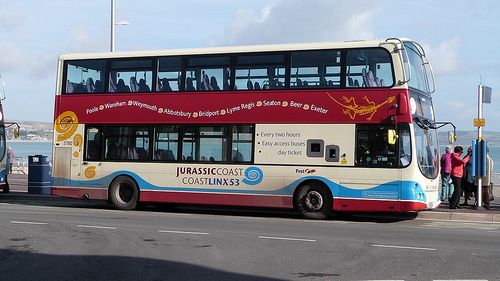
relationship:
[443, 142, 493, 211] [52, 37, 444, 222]
people near bus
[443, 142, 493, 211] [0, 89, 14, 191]
people near bus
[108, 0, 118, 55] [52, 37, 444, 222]
pole behind bus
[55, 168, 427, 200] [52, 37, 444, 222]
blue paint on bus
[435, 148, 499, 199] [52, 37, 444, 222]
group standing near bus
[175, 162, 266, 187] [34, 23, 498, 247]
advertisement on bus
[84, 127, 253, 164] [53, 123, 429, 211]
windows on deck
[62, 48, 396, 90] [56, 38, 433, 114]
windows in top deck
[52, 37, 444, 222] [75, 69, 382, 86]
bus showing passenger seats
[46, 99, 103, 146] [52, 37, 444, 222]
spiral on bus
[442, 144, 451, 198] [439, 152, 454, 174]
person wearing jacket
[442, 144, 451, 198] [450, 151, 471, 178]
person wearing coat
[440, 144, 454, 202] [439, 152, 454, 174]
person wearing jacket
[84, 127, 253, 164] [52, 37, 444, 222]
windows on right side of bus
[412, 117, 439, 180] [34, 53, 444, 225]
windshield of bus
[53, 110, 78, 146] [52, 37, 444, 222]
paint painted on bus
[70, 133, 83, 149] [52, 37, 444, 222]
paint painted on bus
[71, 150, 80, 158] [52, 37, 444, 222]
paint painted on bus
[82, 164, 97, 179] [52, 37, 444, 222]
paint painted on bus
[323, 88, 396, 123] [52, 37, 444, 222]
paint painted on bus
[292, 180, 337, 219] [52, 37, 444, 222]
front wheel mounted on bus